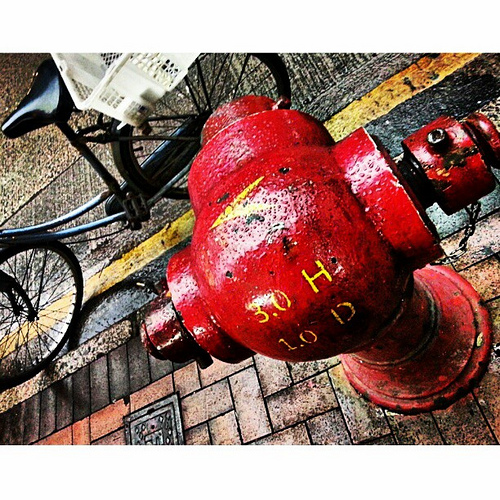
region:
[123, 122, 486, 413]
red color fire hydrant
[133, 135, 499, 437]
fire hydrant kept in the side walk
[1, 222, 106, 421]
front wheel of the cycle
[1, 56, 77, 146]
black color seat in the cycle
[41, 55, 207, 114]
basket in the cycle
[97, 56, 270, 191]
back wheel of the cycle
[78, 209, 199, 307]
road marked with yellow color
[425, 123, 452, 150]
bolt on the fire hydrant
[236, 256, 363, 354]
some numbers and letter written in the fire hydrant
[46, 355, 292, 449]
street walk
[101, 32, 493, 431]
a red fire hydrant.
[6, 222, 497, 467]
a brick sidewalk.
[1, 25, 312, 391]
a bike near a red fire hydrant.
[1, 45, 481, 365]
a yellow line on a road.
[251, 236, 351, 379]
writing on a fire hydrant.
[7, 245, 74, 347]
spokes in a wheel.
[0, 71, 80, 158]
a black bike seat.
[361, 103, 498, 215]
a valve on a fire hydrant.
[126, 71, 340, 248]
a red fire hydrant.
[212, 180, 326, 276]
a wet fire hydrant.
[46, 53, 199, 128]
white plastic basket on the bike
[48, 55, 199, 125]
white milk crate on the back of the bike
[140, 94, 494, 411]
red fire hydrant on the curb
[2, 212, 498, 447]
red brick sidewalk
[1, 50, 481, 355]
yellow stripe on the side of the road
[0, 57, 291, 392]
black bicycle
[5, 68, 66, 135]
black leather seat on a bike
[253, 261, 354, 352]
yellow lettering on a fire hydrant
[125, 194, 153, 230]
bicycle pedal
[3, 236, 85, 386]
front wheel of the bike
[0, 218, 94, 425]
this is a tire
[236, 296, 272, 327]
this is the number 3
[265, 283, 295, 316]
the is the number 0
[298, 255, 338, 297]
this is the letter H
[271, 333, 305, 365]
this is the letter L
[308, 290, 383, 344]
this is the letter D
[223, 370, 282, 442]
this is a brick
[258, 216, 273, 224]
this is the color red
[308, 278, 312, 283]
this is the color yellow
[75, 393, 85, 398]
this is the color gray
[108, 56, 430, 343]
red hydrant in photo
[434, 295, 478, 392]
bottom of the hydrant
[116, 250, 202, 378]
side of the hydrant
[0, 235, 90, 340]
tire on the street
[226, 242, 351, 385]
yellow writing on the hydrant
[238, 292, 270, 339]
the number 3 in yellow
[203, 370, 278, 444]
lines on the ground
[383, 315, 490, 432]
base of the hydrant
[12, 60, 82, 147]
seat of the bike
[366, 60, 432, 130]
yellow line on the street